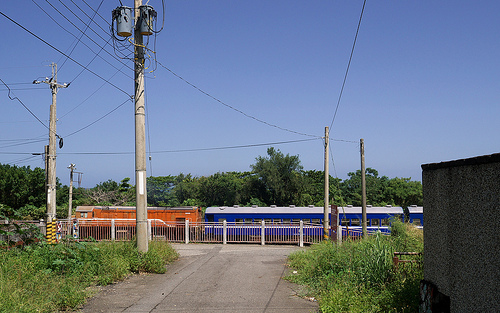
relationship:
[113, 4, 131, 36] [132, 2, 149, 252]
transformer bucket on pole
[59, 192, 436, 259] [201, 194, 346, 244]
train has cars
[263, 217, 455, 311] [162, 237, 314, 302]
green brush side road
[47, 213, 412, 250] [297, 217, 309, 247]
fence has post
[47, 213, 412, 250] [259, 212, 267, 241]
fence has post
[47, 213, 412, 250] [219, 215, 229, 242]
fence has post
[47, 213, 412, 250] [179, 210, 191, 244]
fence has post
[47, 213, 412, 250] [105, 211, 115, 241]
fence has post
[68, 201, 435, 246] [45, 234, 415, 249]
train on tracks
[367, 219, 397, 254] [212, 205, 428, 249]
clock on side of wall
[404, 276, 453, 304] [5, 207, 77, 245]
clock on side of wall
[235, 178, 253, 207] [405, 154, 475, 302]
clock on side of wall